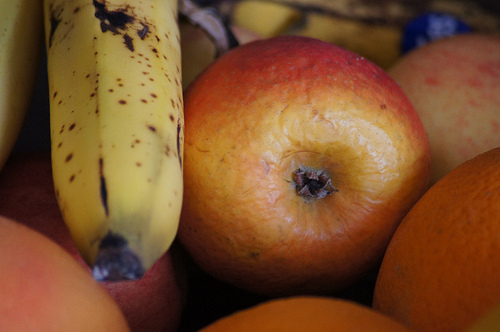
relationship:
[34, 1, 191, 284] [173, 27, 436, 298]
banana near apple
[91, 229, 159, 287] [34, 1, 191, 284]
end of banana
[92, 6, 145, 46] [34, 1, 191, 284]
bruise on banana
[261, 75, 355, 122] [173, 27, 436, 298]
skin on apple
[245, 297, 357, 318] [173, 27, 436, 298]
orange underneath apple